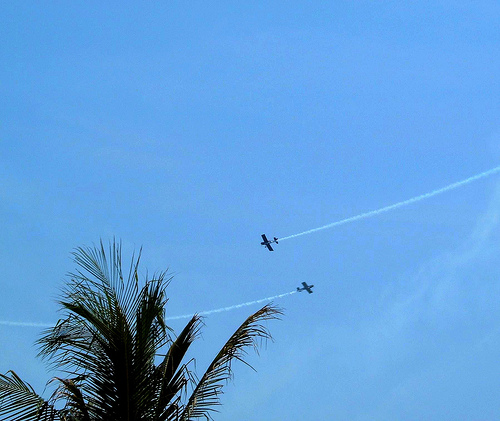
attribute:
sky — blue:
[1, 0, 499, 165]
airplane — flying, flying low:
[260, 231, 279, 254]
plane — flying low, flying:
[297, 280, 315, 295]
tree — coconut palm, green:
[0, 254, 283, 420]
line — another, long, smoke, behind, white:
[279, 164, 498, 243]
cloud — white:
[417, 202, 497, 309]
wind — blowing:
[1, 1, 499, 420]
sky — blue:
[1, 1, 498, 235]